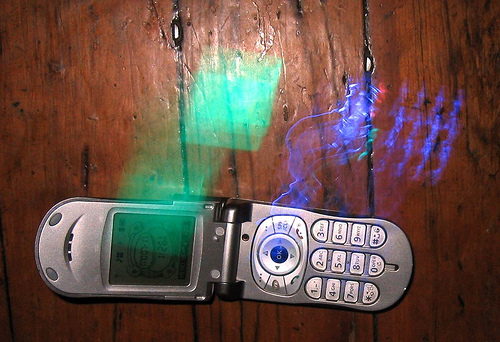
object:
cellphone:
[34, 193, 416, 312]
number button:
[304, 277, 322, 300]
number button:
[332, 215, 349, 247]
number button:
[325, 279, 341, 301]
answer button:
[284, 267, 305, 296]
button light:
[273, 215, 294, 235]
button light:
[310, 219, 328, 243]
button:
[272, 215, 294, 234]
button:
[368, 254, 385, 277]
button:
[310, 248, 328, 270]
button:
[343, 281, 358, 304]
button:
[349, 252, 366, 275]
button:
[350, 223, 367, 246]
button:
[370, 225, 386, 248]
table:
[0, 0, 500, 342]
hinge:
[215, 200, 246, 298]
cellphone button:
[269, 245, 287, 262]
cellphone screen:
[107, 212, 196, 286]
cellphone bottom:
[249, 214, 388, 307]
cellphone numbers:
[305, 219, 388, 304]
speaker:
[65, 228, 73, 263]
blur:
[256, 70, 467, 261]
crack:
[361, 0, 377, 217]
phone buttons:
[265, 276, 287, 300]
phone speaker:
[384, 263, 400, 272]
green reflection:
[117, 41, 282, 202]